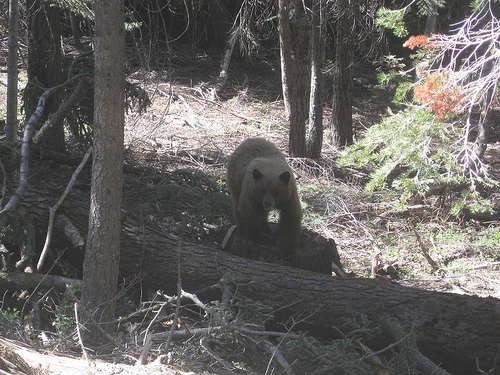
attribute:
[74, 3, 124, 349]
trunks — in the picture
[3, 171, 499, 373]
trunk — fallen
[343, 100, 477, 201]
leaves — in the picture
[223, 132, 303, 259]
bear — brown, in the picture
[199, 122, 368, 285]
bear — large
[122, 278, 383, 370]
sticks — various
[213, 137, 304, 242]
bear — in the picture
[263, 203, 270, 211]
nose — black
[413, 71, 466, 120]
leaves — in the picture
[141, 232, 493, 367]
tree trunk — fallen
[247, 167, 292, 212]
head — in the picture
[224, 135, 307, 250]
bear — in the picture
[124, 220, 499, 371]
log — in the picture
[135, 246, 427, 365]
ground — in the picture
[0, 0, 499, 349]
trees — in the picture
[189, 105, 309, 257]
bear — large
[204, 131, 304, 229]
bear — in the picture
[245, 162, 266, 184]
ear — black